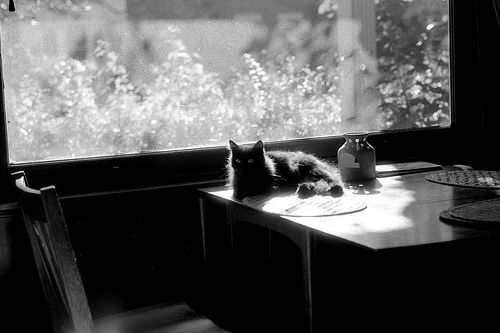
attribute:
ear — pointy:
[229, 140, 240, 151]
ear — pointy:
[253, 139, 262, 147]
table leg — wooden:
[301, 226, 313, 331]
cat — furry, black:
[229, 136, 346, 203]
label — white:
[338, 150, 360, 170]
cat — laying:
[191, 112, 383, 218]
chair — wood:
[10, 153, 199, 331]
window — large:
[4, 0, 461, 171]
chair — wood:
[10, 159, 215, 326]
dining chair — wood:
[6, 164, 222, 331]